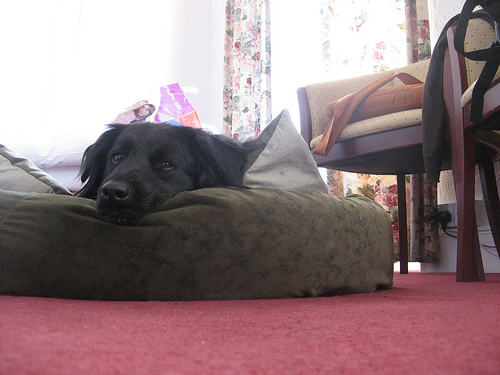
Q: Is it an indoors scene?
A: Yes, it is indoors.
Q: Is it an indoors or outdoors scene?
A: It is indoors.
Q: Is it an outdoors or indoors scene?
A: It is indoors.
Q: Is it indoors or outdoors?
A: It is indoors.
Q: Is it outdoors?
A: No, it is indoors.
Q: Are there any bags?
A: Yes, there is a bag.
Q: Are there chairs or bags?
A: Yes, there is a bag.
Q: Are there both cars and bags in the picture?
A: No, there is a bag but no cars.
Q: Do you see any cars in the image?
A: No, there are no cars.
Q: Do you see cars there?
A: No, there are no cars.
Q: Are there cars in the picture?
A: No, there are no cars.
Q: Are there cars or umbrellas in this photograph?
A: No, there are no cars or umbrellas.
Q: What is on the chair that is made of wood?
A: The bag is on the chair.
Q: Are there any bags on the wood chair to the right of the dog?
A: Yes, there is a bag on the chair.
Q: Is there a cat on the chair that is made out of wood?
A: No, there is a bag on the chair.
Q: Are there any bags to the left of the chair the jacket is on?
A: Yes, there is a bag to the left of the chair.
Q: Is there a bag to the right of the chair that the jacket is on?
A: No, the bag is to the left of the chair.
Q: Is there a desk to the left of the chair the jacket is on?
A: No, there is a bag to the left of the chair.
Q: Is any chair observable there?
A: Yes, there is a chair.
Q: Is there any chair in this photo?
A: Yes, there is a chair.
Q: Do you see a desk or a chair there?
A: Yes, there is a chair.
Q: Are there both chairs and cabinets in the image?
A: No, there is a chair but no cabinets.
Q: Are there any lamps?
A: No, there are no lamps.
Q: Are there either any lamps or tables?
A: No, there are no lamps or tables.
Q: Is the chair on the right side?
A: Yes, the chair is on the right of the image.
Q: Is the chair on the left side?
A: No, the chair is on the right of the image.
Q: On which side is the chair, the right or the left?
A: The chair is on the right of the image.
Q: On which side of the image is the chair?
A: The chair is on the right of the image.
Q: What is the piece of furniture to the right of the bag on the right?
A: The piece of furniture is a chair.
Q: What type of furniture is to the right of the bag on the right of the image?
A: The piece of furniture is a chair.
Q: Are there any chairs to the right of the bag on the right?
A: Yes, there is a chair to the right of the bag.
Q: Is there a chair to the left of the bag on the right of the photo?
A: No, the chair is to the right of the bag.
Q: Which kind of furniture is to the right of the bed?
A: The piece of furniture is a chair.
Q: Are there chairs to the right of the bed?
A: Yes, there is a chair to the right of the bed.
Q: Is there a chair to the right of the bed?
A: Yes, there is a chair to the right of the bed.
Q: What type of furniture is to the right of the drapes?
A: The piece of furniture is a chair.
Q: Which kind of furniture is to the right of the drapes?
A: The piece of furniture is a chair.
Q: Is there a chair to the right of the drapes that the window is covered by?
A: Yes, there is a chair to the right of the drapes.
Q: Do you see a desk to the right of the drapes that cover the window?
A: No, there is a chair to the right of the draperies.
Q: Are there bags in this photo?
A: Yes, there is a bag.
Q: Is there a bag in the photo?
A: Yes, there is a bag.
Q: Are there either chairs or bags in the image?
A: Yes, there is a bag.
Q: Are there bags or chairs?
A: Yes, there is a bag.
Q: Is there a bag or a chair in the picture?
A: Yes, there is a bag.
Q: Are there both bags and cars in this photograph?
A: No, there is a bag but no cars.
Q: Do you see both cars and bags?
A: No, there is a bag but no cars.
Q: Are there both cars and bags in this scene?
A: No, there is a bag but no cars.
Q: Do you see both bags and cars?
A: No, there is a bag but no cars.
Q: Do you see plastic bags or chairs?
A: Yes, there is a plastic bag.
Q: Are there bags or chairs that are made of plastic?
A: Yes, the bag is made of plastic.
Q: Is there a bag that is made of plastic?
A: Yes, there is a bag that is made of plastic.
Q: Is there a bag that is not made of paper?
A: Yes, there is a bag that is made of plastic.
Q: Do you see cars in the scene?
A: No, there are no cars.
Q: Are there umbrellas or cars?
A: No, there are no cars or umbrellas.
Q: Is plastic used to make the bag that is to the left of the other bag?
A: Yes, the bag is made of plastic.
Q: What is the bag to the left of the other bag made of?
A: The bag is made of plastic.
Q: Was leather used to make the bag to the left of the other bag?
A: No, the bag is made of plastic.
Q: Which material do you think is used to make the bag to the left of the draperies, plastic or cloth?
A: The bag is made of plastic.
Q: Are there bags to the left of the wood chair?
A: Yes, there is a bag to the left of the chair.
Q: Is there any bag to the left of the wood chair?
A: Yes, there is a bag to the left of the chair.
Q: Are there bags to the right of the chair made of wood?
A: No, the bag is to the left of the chair.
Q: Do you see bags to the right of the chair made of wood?
A: No, the bag is to the left of the chair.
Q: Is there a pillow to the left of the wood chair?
A: No, there is a bag to the left of the chair.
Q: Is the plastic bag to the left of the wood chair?
A: Yes, the bag is to the left of the chair.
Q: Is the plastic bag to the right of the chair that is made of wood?
A: No, the bag is to the left of the chair.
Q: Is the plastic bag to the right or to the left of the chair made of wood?
A: The bag is to the left of the chair.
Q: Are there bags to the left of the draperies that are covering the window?
A: Yes, there is a bag to the left of the draperies.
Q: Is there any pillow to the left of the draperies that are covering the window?
A: No, there is a bag to the left of the drapes.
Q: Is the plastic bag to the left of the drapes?
A: Yes, the bag is to the left of the drapes.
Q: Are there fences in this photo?
A: No, there are no fences.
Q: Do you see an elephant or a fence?
A: No, there are no fences or elephants.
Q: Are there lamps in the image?
A: No, there are no lamps.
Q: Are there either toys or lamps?
A: No, there are no lamps or toys.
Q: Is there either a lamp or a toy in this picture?
A: No, there are no lamps or toys.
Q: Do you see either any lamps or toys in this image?
A: No, there are no lamps or toys.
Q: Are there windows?
A: Yes, there is a window.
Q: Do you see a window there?
A: Yes, there is a window.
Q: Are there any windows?
A: Yes, there is a window.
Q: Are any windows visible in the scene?
A: Yes, there is a window.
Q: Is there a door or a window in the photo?
A: Yes, there is a window.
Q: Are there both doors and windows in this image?
A: No, there is a window but no doors.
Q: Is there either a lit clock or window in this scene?
A: Yes, there is a lit window.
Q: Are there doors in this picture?
A: No, there are no doors.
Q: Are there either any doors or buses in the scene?
A: No, there are no doors or buses.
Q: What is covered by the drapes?
A: The window is covered by the drapes.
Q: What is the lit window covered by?
A: The window is covered by the drapes.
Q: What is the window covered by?
A: The window is covered by the drapes.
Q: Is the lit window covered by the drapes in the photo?
A: Yes, the window is covered by the drapes.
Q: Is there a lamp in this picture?
A: No, there are no lamps.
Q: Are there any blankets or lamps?
A: No, there are no lamps or blankets.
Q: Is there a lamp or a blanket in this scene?
A: No, there are no lamps or blankets.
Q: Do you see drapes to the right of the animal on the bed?
A: Yes, there are drapes to the right of the dog.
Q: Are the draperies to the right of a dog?
A: Yes, the draperies are to the right of a dog.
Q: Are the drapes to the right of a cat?
A: No, the drapes are to the right of a dog.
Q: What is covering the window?
A: The draperies are covering the window.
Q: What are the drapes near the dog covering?
A: The draperies are covering the window.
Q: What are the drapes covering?
A: The draperies are covering the window.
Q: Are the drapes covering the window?
A: Yes, the drapes are covering the window.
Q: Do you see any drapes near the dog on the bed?
A: Yes, there are drapes near the dog.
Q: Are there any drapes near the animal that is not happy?
A: Yes, there are drapes near the dog.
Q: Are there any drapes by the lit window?
A: Yes, there are drapes by the window.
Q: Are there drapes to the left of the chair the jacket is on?
A: Yes, there are drapes to the left of the chair.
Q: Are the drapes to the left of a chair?
A: Yes, the drapes are to the left of a chair.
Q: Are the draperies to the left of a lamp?
A: No, the draperies are to the left of a chair.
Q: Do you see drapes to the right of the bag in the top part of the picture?
A: Yes, there are drapes to the right of the bag.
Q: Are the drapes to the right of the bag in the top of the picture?
A: Yes, the drapes are to the right of the bag.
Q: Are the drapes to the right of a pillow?
A: No, the drapes are to the right of the bag.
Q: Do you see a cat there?
A: No, there are no cats.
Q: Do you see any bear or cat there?
A: No, there are no cats or bears.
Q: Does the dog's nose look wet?
A: Yes, the nose is wet.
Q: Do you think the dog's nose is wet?
A: Yes, the nose is wet.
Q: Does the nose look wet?
A: Yes, the nose is wet.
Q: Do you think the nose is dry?
A: No, the nose is wet.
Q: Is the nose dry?
A: No, the nose is wet.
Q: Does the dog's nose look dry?
A: No, the nose is wet.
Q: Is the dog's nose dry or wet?
A: The nose is wet.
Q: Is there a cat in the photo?
A: No, there are no cats.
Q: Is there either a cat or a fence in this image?
A: No, there are no cats or fences.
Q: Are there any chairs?
A: Yes, there is a chair.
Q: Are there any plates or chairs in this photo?
A: Yes, there is a chair.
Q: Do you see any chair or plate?
A: Yes, there is a chair.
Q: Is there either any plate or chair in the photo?
A: Yes, there is a chair.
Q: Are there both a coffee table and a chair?
A: No, there is a chair but no coffee tables.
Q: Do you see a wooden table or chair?
A: Yes, there is a wood chair.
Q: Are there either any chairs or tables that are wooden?
A: Yes, the chair is wooden.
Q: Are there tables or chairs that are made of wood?
A: Yes, the chair is made of wood.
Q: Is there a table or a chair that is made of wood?
A: Yes, the chair is made of wood.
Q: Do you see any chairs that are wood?
A: Yes, there is a wood chair.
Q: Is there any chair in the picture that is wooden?
A: Yes, there is a chair that is wooden.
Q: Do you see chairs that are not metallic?
A: Yes, there is a wooden chair.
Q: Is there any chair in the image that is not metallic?
A: Yes, there is a wooden chair.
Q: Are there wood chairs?
A: Yes, there is a chair that is made of wood.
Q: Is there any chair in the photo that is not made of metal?
A: Yes, there is a chair that is made of wood.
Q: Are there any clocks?
A: No, there are no clocks.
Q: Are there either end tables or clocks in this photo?
A: No, there are no clocks or end tables.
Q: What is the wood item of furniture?
A: The piece of furniture is a chair.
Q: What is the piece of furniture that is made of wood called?
A: The piece of furniture is a chair.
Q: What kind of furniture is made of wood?
A: The furniture is a chair.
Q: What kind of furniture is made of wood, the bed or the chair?
A: The chair is made of wood.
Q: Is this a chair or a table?
A: This is a chair.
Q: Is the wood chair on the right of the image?
A: Yes, the chair is on the right of the image.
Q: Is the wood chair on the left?
A: No, the chair is on the right of the image.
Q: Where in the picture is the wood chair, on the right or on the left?
A: The chair is on the right of the image.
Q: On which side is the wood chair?
A: The chair is on the right of the image.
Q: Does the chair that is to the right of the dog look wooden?
A: Yes, the chair is wooden.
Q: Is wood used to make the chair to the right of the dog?
A: Yes, the chair is made of wood.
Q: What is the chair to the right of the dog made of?
A: The chair is made of wood.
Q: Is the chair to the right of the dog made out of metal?
A: No, the chair is made of wood.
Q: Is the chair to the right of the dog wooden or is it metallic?
A: The chair is wooden.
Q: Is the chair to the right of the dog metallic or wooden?
A: The chair is wooden.